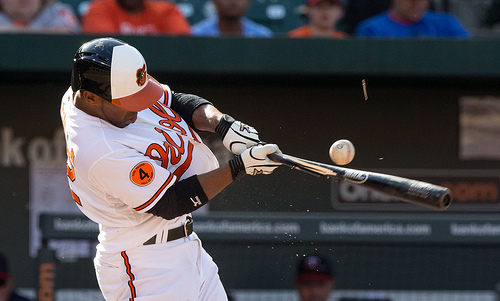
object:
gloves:
[240, 143, 283, 175]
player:
[60, 36, 282, 300]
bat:
[266, 151, 455, 211]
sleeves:
[170, 92, 214, 132]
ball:
[327, 139, 356, 166]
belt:
[143, 218, 193, 245]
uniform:
[60, 84, 230, 300]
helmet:
[73, 37, 164, 112]